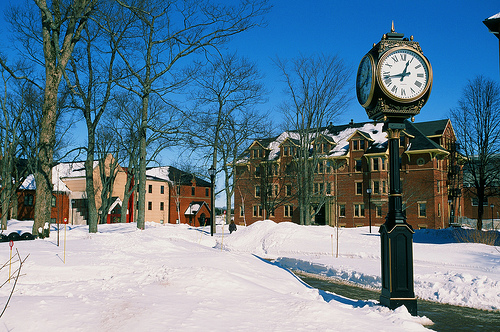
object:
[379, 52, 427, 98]
face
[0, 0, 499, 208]
sky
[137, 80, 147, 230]
tree trunk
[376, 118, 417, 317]
pole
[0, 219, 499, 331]
snow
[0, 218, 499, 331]
ground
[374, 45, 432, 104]
clock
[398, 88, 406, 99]
numerals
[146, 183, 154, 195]
window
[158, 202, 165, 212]
window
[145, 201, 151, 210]
window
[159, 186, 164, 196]
window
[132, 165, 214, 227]
building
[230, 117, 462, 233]
building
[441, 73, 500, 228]
tree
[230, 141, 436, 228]
walls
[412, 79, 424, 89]
numerals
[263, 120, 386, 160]
snow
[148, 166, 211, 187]
roof